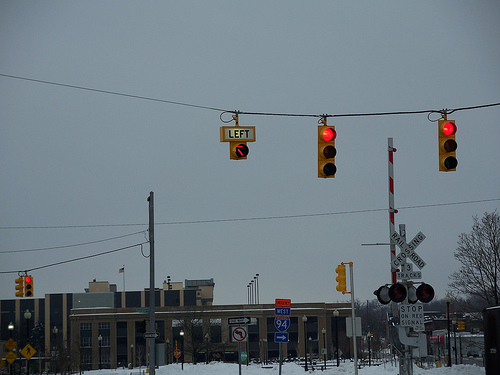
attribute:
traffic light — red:
[434, 119, 460, 173]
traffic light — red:
[315, 124, 338, 181]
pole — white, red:
[385, 136, 403, 283]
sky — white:
[1, 1, 497, 304]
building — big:
[1, 278, 360, 374]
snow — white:
[83, 357, 485, 373]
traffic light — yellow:
[14, 274, 24, 299]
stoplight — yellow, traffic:
[22, 275, 37, 299]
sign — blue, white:
[274, 309, 290, 345]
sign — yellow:
[19, 345, 39, 360]